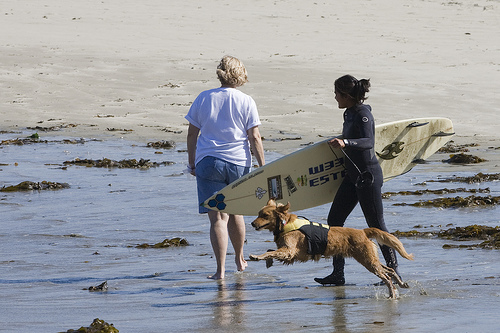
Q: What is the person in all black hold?
A: A surfboard.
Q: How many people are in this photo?
A: Two.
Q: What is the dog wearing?
A: A water vest.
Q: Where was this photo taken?
A: The beach.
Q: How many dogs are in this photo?
A: One.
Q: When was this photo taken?
A: Outside, during the daytime.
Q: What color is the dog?
A: Brown.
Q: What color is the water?
A: Blue.